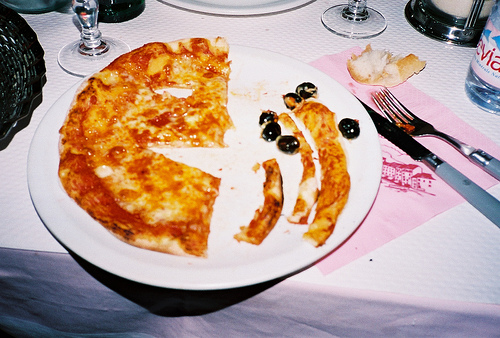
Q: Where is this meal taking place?
A: A restaurant.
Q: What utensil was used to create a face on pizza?
A: Knife.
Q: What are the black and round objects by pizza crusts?
A: Olives.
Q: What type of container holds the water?
A: Bottle.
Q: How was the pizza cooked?
A: Baked.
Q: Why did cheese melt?
A: High heat.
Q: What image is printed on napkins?
A: Buildings.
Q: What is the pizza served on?
A: Large round white plate.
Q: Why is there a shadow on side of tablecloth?
A: Plate leaning over the edge.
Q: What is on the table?
A: The white paper plate.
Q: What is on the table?
A: Pink napkin.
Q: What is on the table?
A: The knife.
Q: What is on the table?
A: The fork.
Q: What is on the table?
A: Fork and knife.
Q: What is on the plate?
A: Cheese pizza pie.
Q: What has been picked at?
A: The pizza.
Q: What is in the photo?
A: Knife and fork.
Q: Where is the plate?
A: On the table.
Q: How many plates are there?
A: One.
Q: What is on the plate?
A: A pancake.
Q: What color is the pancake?
A: Brown.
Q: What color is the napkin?
A: Pink.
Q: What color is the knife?
A: Blue and silver.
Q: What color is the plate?
A: White.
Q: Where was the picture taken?
A: At a dinner table.